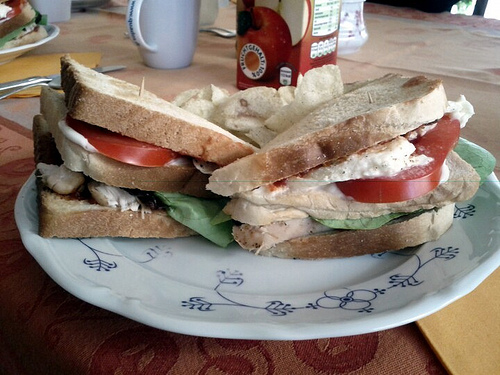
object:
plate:
[10, 123, 500, 340]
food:
[32, 54, 498, 259]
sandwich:
[213, 70, 463, 260]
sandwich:
[31, 51, 258, 236]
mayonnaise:
[58, 117, 96, 150]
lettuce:
[154, 192, 233, 247]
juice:
[237, 0, 338, 89]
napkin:
[0, 47, 105, 99]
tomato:
[333, 120, 463, 204]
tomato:
[65, 113, 183, 168]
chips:
[210, 86, 297, 133]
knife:
[1, 60, 129, 106]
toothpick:
[138, 73, 146, 96]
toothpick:
[366, 91, 373, 103]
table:
[1, 1, 498, 373]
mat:
[413, 259, 498, 374]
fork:
[1, 59, 126, 102]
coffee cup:
[125, 0, 201, 71]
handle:
[125, 0, 158, 53]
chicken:
[244, 173, 482, 243]